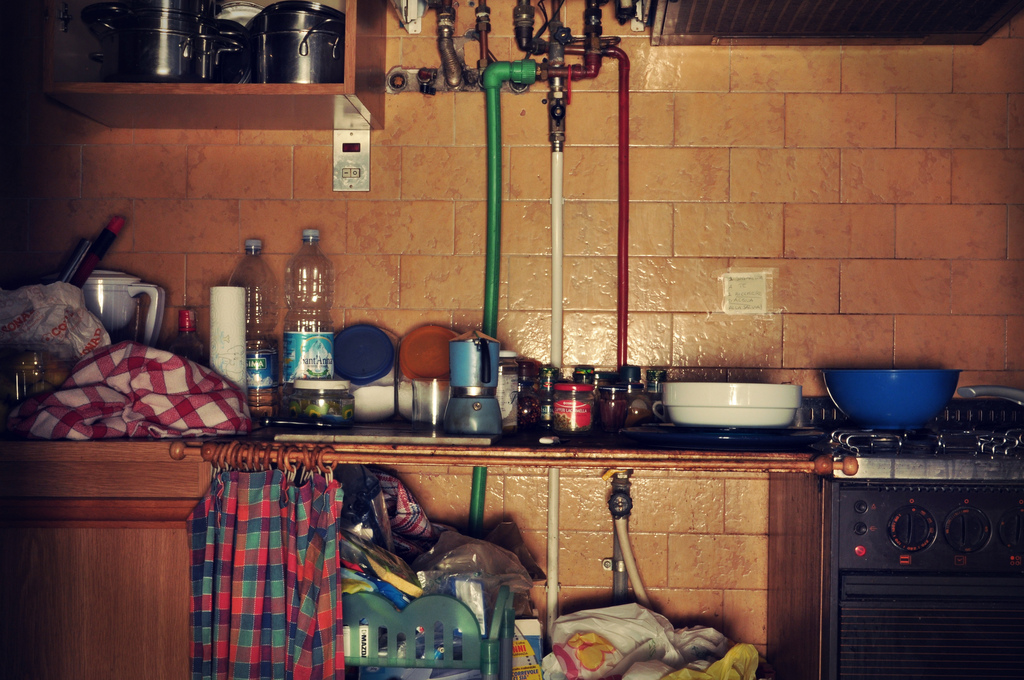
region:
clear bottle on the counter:
[279, 212, 333, 384]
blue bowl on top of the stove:
[807, 339, 963, 439]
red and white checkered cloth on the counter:
[4, 342, 260, 447]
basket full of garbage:
[349, 582, 509, 677]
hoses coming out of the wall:
[589, 477, 659, 596]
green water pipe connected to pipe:
[473, 57, 527, 339]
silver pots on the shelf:
[74, 9, 349, 87]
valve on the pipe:
[389, 66, 406, 92]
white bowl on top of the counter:
[664, 357, 802, 431]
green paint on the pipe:
[481, 60, 529, 340]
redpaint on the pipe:
[598, 49, 656, 373]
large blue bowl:
[826, 357, 957, 437]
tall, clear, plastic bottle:
[288, 219, 342, 423]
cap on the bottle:
[296, 219, 339, 240]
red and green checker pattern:
[181, 453, 359, 678]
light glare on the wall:
[517, 303, 661, 365]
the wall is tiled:
[7, 4, 1020, 678]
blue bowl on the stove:
[820, 347, 960, 433]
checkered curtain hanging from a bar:
[187, 458, 343, 673]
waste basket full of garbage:
[345, 476, 510, 677]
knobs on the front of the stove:
[880, 497, 995, 562]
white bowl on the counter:
[664, 372, 801, 430]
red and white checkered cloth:
[23, 335, 254, 447]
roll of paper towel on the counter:
[207, 268, 253, 389]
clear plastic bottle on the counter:
[267, 214, 329, 388]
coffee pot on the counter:
[437, 322, 499, 433]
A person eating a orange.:
[519, 271, 750, 388]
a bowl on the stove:
[836, 332, 993, 492]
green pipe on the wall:
[443, 31, 542, 437]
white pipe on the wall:
[532, 82, 594, 390]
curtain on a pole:
[195, 426, 361, 677]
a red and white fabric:
[41, 315, 285, 484]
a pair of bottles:
[187, 193, 350, 438]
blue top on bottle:
[285, 211, 328, 244]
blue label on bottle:
[285, 328, 337, 373]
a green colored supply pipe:
[466, 62, 542, 556]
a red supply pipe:
[566, 27, 628, 363]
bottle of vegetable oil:
[276, 231, 335, 390]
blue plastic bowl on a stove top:
[816, 346, 965, 426]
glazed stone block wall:
[0, 38, 1016, 643]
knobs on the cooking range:
[856, 505, 1022, 570]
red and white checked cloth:
[21, 336, 256, 442]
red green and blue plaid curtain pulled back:
[196, 432, 351, 676]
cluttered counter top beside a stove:
[0, 202, 811, 466]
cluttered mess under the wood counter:
[334, 467, 772, 677]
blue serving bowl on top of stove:
[827, 363, 963, 437]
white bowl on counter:
[653, 373, 812, 435]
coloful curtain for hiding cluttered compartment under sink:
[193, 468, 349, 674]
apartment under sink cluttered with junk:
[328, 461, 831, 676]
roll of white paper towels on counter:
[208, 279, 248, 398]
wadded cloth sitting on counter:
[4, 283, 258, 448]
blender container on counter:
[82, 268, 169, 354]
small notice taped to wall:
[711, 258, 778, 320]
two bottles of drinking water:
[225, 224, 339, 420]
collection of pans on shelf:
[0, 0, 343, 84]